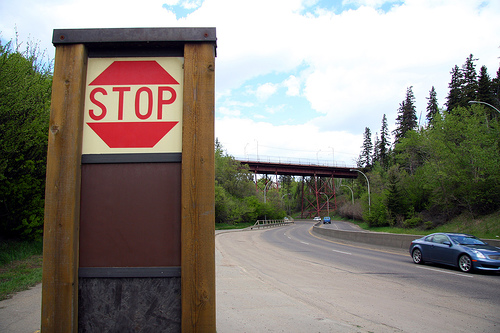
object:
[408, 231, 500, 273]
pink shirt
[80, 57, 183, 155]
sign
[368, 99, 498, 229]
pines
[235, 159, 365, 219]
bridge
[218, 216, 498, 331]
highway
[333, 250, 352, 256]
line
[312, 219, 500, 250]
barrier wall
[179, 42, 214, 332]
post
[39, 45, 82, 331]
post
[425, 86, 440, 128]
tall trees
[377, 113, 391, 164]
tall trees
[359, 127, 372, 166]
tall trees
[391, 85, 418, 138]
tall trees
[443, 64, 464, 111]
tall trees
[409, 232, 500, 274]
car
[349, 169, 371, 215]
post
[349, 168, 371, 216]
street light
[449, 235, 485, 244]
window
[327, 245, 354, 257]
line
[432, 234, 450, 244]
window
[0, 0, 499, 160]
white cloud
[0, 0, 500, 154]
blue sky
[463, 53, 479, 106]
trees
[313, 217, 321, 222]
car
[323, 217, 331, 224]
car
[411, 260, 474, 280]
line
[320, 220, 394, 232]
lane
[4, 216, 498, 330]
ground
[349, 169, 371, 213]
light post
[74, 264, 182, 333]
bottom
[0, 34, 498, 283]
park